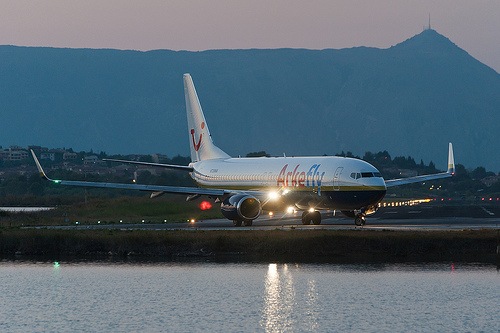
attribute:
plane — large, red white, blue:
[30, 72, 455, 227]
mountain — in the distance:
[0, 28, 499, 174]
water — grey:
[0, 249, 499, 331]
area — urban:
[1, 145, 170, 178]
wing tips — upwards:
[30, 151, 56, 184]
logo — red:
[190, 118, 208, 152]